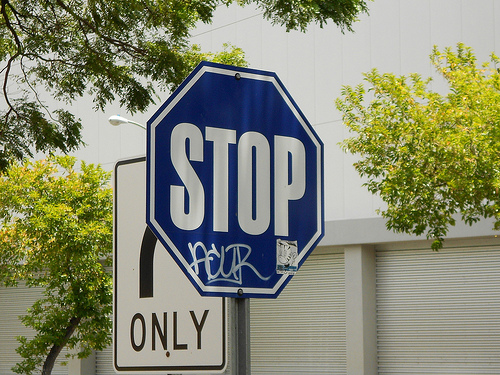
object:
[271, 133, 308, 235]
letter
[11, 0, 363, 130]
branches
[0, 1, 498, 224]
sky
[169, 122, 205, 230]
letter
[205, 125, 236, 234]
letter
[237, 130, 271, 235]
letter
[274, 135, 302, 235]
letter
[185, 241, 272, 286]
letter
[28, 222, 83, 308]
branch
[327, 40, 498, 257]
tree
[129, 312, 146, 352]
letter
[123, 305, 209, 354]
word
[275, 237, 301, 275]
square sticker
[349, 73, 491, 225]
branch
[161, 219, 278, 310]
graffiti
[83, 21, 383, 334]
sign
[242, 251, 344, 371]
door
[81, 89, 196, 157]
street lamp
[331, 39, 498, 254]
leaves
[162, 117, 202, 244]
letter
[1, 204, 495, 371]
building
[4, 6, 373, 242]
tree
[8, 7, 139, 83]
leaves